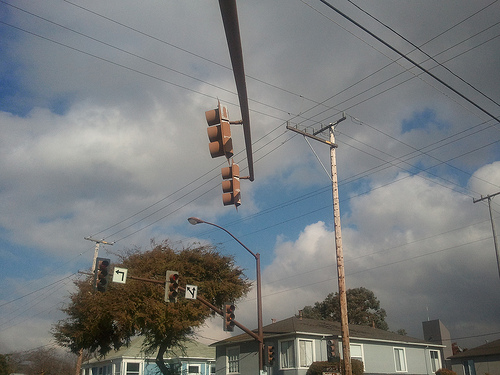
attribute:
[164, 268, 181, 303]
traffic signal — red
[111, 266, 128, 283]
sign — white, black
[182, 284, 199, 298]
sign — white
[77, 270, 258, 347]
arm — gray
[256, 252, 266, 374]
pole — gray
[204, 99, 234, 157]
traffic signal — metal, rusted, brown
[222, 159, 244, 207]
traffic signal — brown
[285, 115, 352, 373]
utility pole — wooden, brown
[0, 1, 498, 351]
sky — cloudy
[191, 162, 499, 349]
clouds — white, large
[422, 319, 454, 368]
building — tall, gray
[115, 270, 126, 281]
arrow — black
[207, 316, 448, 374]
house — gray, blue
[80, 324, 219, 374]
house — blue, trimmed in white, light blue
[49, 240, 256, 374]
tree — large, tall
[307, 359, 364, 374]
bush — green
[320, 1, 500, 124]
power line — thick, black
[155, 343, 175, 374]
trunk — crooked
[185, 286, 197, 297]
arrows — black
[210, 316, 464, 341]
roof — black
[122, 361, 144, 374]
window — white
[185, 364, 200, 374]
window — white